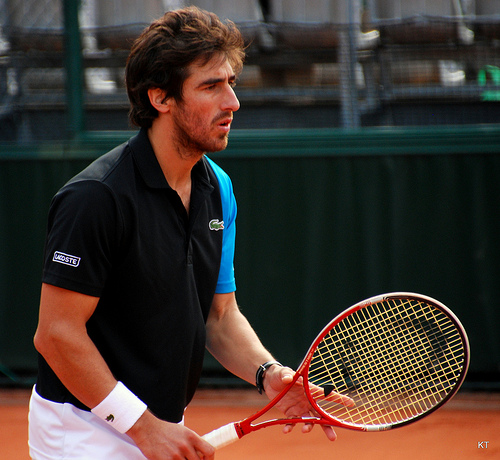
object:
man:
[27, 6, 357, 460]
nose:
[220, 81, 241, 112]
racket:
[193, 290, 471, 460]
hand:
[142, 421, 217, 460]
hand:
[261, 364, 354, 440]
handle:
[201, 418, 248, 450]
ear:
[147, 86, 172, 112]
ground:
[0, 384, 498, 460]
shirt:
[33, 129, 238, 422]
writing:
[52, 251, 82, 267]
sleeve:
[205, 161, 239, 295]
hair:
[124, 4, 245, 129]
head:
[124, 7, 248, 152]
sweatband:
[90, 378, 148, 436]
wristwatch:
[255, 357, 281, 395]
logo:
[208, 217, 225, 231]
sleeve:
[41, 183, 118, 298]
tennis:
[197, 289, 471, 460]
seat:
[0, 91, 495, 136]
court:
[0, 386, 499, 460]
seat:
[0, 45, 499, 96]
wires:
[308, 294, 461, 427]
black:
[136, 251, 168, 359]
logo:
[104, 414, 117, 423]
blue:
[223, 183, 234, 283]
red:
[236, 420, 253, 436]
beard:
[171, 105, 231, 159]